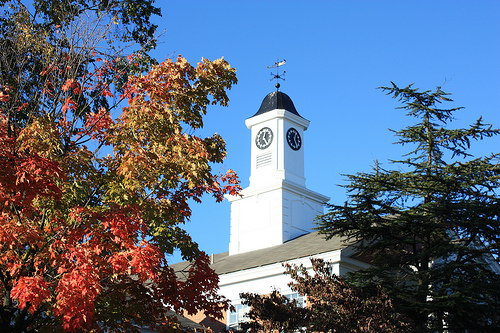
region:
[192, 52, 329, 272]
a white clock tower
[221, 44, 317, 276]
a white clock tower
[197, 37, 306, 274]
a white clock tower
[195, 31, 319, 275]
a white clock tower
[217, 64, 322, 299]
a white clock tower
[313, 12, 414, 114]
the sky is clear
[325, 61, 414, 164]
the sky is clear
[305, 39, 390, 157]
the sky is clear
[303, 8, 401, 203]
the sky is clear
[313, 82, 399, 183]
the sky is clear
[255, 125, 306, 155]
Clocks on a white tower top.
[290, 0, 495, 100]
The sky is clear and blue.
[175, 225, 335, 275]
Roof is grey colored.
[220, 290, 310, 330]
White framed glass windows.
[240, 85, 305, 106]
Top roof of the tower is black.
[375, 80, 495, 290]
Tall green pine tree in the garden.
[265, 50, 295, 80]
Tower topped with an iron wind vane.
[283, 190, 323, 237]
White painted tower with design.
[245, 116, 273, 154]
clock in tower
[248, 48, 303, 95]
weather vane on top of tower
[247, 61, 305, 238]
white clock tower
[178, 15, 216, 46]
white clouds in blue sky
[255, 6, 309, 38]
white clouds in blue sky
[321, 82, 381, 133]
white clouds in blue sky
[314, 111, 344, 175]
white clouds in blue sky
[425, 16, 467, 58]
white clouds in blue sky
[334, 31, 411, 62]
white clouds in blue sky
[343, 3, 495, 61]
The sky is blue.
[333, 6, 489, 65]
The sky is clear.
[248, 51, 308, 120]
The steeple is black.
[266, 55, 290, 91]
The weather spire is silver.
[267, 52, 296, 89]
The weather spire is made of metal.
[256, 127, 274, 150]
The clock face is black.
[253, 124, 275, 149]
The clock hands are white.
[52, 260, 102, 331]
The tree leaves are red.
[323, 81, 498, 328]
The tree is green.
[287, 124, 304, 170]
There is a clock that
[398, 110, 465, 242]
There is a green tree that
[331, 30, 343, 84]
There is a dark blue sky visible here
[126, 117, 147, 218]
There are some light leaves visible here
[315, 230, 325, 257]
There is some black tiles on this building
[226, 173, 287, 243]
There is white that is visible here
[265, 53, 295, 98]
There is a directional wind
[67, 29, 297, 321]
Jackson Mingus knows this photo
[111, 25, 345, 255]
This was taken in Vermont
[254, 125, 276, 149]
tower has a clock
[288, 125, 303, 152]
tower has a clock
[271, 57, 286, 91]
tower has a sign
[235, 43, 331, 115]
top of the building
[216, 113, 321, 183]
clocks on the building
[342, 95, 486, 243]
tree next to building